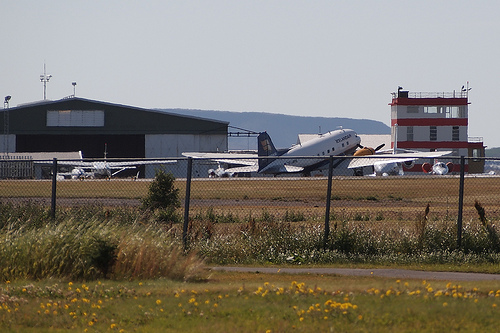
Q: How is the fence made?
A: Chain link.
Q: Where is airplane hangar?
A: On left.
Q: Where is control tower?
A: On right.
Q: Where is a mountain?
A: In the distant.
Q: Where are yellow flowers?
A: Field in foreground.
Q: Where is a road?
A: Between field and fence.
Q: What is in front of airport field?
A: Chain link fence.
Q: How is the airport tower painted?
A: Red and white.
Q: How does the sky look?
A: Clear and no clouds.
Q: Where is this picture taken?
A: At the airport.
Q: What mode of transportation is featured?
A: An airplane.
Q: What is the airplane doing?
A: It is parked.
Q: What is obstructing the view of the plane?
A: A fence.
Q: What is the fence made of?
A: Wire.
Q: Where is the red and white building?
A: To the right of the plane.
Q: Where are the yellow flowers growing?
A: In the grass.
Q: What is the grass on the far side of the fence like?
A: Short and brown.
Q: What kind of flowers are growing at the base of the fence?
A: White flowers.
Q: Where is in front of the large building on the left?
A: Another airplane.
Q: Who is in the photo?
A: No people.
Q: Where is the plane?
A: On the ground.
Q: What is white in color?
A: The plane.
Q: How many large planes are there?
A: One.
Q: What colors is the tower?
A: Red and white.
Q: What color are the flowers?
A: Yellow.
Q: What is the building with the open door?
A: A hangar.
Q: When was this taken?
A: Daytime.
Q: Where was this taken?
A: At the airport.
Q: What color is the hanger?
A: White and grey.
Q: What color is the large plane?
A: White.